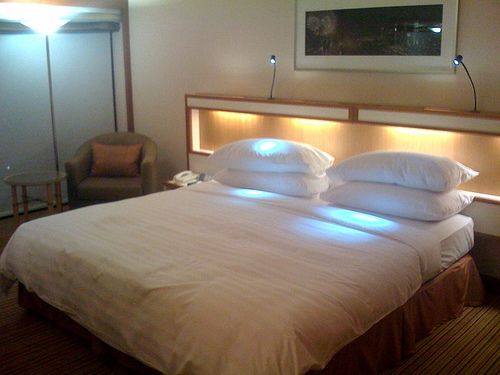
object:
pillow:
[328, 152, 480, 192]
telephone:
[171, 170, 201, 185]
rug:
[381, 290, 500, 375]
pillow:
[90, 142, 145, 179]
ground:
[370, 299, 499, 373]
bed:
[7, 139, 424, 356]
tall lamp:
[19, 13, 75, 37]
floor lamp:
[21, 4, 70, 209]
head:
[183, 88, 498, 231]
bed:
[13, 175, 477, 373]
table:
[4, 167, 68, 228]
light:
[19, 12, 77, 163]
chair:
[63, 126, 163, 204]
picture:
[293, 0, 462, 76]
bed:
[18, 175, 479, 375]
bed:
[3, 106, 447, 328]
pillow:
[208, 138, 334, 179]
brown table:
[7, 171, 68, 225]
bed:
[98, 179, 396, 330]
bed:
[5, 177, 479, 371]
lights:
[296, 203, 400, 242]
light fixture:
[266, 55, 279, 100]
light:
[253, 136, 286, 157]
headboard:
[184, 86, 496, 235]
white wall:
[130, 0, 497, 192]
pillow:
[211, 168, 330, 198]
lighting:
[230, 186, 273, 198]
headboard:
[181, 92, 499, 198]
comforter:
[0, 179, 445, 374]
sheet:
[0, 181, 441, 375]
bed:
[43, 208, 495, 360]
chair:
[52, 116, 166, 190]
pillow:
[319, 181, 475, 222]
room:
[0, 0, 500, 375]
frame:
[293, 3, 460, 71]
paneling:
[186, 91, 497, 235]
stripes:
[435, 301, 500, 371]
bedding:
[1, 137, 478, 373]